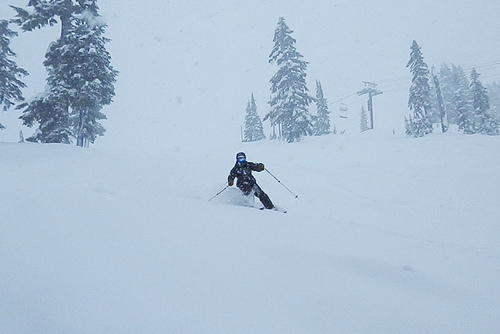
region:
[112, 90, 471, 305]
a person skiing on the snow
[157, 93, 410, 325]
a person skiing on a hill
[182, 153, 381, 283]
a person skiing on a mountain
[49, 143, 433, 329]
a snow covered ground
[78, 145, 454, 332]
a white snow covered ground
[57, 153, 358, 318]
a ground covered in snow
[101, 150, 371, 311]
a ground covered in white snow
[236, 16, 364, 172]
trees covered in snow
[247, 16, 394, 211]
trees covered in white snow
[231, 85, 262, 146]
Tree in the back with a lot of snow.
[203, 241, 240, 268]
Tree in the back with a lot of snow.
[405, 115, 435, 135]
Tree in the back with a lot of snow.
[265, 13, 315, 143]
snow covered pine tree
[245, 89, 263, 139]
snow covered pine tree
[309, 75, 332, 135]
snow covered pine tree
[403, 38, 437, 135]
snow covered pine tree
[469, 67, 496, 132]
snow covered pine tree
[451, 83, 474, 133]
snow covered pine tree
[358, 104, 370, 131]
snow covered pine tree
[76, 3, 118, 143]
snow covered pine tree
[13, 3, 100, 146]
snow covered pine tree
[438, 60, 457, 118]
snow covered pine tree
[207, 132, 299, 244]
a skier coming down a trail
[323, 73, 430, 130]
a chairlift on a mountain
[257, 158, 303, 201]
a hand holding a ski pole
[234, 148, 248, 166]
the head of a person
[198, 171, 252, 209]
a dust of snow behind a skier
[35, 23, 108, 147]
evergreen trees with snow on them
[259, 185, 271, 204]
a person's left leg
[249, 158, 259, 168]
a person's left arm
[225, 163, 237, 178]
a person's right arm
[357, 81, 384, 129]
a tower suspending chairlift cables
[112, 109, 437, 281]
a person that is skiing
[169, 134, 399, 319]
a person that is on skies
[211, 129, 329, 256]
a person sking on a mountain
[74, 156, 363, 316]
ground covered in white snow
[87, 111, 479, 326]
snow covering the ground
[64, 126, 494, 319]
white snow covering the ground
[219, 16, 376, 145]
snow covering the trees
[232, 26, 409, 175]
white snow covered on trees